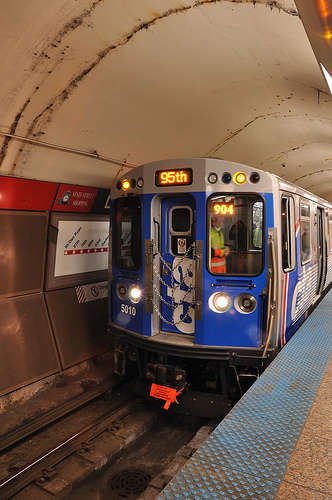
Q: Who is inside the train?
A: Two people.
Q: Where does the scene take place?
A: In train station.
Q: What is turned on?
A: Train's headlights.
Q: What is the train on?
A: Train tracks.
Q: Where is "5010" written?
A: On front of train.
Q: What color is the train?
A: Blue.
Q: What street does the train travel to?
A: 95th street.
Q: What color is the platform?
A: Blue and beige.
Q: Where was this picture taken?
A: A subway station.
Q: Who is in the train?
A: The conductor.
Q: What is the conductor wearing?
A: A safety vest.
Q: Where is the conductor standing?
A: The front of the train.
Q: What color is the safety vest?
A: Yellow and orange.